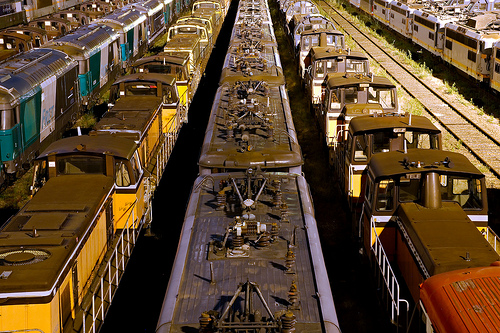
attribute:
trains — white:
[150, 7, 343, 303]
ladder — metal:
[365, 219, 408, 312]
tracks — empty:
[330, 11, 491, 185]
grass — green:
[380, 41, 494, 117]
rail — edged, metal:
[362, 54, 498, 118]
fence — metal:
[149, 107, 218, 199]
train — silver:
[10, 23, 134, 114]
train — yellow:
[60, 8, 211, 191]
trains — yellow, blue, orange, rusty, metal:
[3, 0, 227, 299]